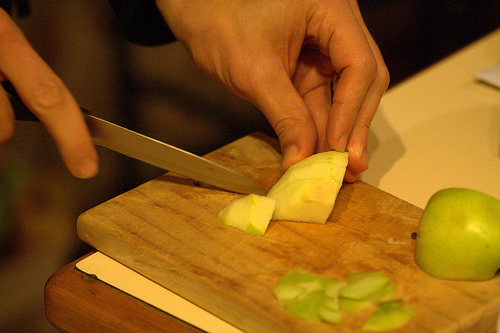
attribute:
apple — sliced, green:
[412, 186, 499, 280]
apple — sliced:
[219, 150, 499, 282]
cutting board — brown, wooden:
[76, 131, 500, 332]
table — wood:
[42, 29, 499, 331]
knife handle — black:
[0, 82, 91, 131]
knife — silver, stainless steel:
[1, 78, 265, 194]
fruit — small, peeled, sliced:
[219, 151, 350, 238]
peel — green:
[272, 268, 417, 331]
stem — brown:
[409, 231, 420, 240]